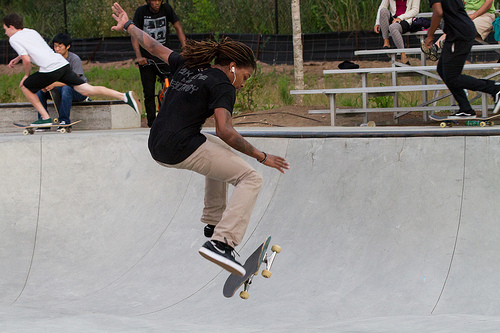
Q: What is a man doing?
A: Skateboarding.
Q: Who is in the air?
A: A skateboarder.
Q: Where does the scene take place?
A: At a skateboard park.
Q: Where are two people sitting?
A: On bleachers.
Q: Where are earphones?
A: In skateboarder's ears.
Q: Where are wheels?
A: On the skateboard.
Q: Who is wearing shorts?
A: Skateboarder in white shirt.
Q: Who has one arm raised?
A: Skateboarder in the air.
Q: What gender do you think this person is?
A: Male.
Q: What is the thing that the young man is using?
A: Skateboard.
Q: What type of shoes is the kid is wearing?
A: Skater shoes.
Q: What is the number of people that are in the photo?
A: 7.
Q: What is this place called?
A: The skate park.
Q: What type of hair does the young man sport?
A: Dreadlocks.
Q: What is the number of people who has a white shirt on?
A: One.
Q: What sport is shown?
A: Skateboarding.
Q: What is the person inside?
A: Bowl.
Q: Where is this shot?
A: Skate park.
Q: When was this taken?
A: Daytime.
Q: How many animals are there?
A: 0.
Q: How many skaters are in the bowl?
A: 1.